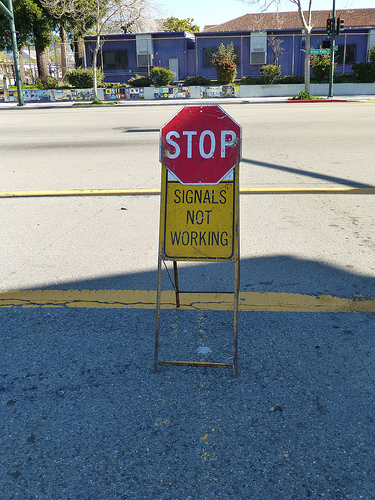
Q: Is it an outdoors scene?
A: Yes, it is outdoors.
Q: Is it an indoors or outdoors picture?
A: It is outdoors.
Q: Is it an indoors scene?
A: No, it is outdoors.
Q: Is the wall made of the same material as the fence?
A: No, the wall is made of cement and the fence is made of metal.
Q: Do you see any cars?
A: No, there are no cars.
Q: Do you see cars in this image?
A: No, there are no cars.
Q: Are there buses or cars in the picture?
A: No, there are no cars or buses.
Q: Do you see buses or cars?
A: No, there are no cars or buses.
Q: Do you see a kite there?
A: No, there are no kites.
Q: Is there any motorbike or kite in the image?
A: No, there are no kites or motorcycles.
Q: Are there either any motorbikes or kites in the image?
A: No, there are no kites or motorbikes.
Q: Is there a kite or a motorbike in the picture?
A: No, there are no kites or motorcycles.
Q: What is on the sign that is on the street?
A: The letter is on the stop sign.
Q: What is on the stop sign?
A: The letter is on the stop sign.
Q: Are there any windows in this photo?
A: Yes, there is a window.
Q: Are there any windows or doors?
A: Yes, there is a window.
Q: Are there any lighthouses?
A: No, there are no lighthouses.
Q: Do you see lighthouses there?
A: No, there are no lighthouses.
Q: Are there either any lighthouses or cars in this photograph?
A: No, there are no lighthouses or cars.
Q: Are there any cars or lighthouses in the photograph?
A: No, there are no lighthouses or cars.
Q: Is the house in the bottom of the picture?
A: No, the house is in the top of the image.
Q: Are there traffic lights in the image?
A: Yes, there is a traffic light.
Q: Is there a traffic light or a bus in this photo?
A: Yes, there is a traffic light.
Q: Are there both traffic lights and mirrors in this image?
A: No, there is a traffic light but no mirrors.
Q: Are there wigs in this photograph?
A: No, there are no wigs.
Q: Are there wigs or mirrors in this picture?
A: No, there are no wigs or mirrors.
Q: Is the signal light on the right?
A: Yes, the signal light is on the right of the image.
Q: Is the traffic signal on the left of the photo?
A: No, the traffic signal is on the right of the image.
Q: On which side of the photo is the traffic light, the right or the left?
A: The traffic light is on the right of the image.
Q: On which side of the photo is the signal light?
A: The signal light is on the right of the image.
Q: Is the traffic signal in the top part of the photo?
A: Yes, the traffic signal is in the top of the image.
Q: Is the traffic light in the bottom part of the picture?
A: No, the traffic light is in the top of the image.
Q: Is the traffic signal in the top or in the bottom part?
A: The traffic signal is in the top of the image.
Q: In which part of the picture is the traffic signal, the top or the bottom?
A: The traffic signal is in the top of the image.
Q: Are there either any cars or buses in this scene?
A: No, there are no cars or buses.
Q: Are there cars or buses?
A: No, there are no cars or buses.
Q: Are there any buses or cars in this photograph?
A: No, there are no cars or buses.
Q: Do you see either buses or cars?
A: No, there are no cars or buses.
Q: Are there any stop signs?
A: Yes, there is a stop sign.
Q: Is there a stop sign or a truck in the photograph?
A: Yes, there is a stop sign.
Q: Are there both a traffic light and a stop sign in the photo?
A: Yes, there are both a stop sign and a traffic light.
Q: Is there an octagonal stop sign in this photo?
A: Yes, there is an octagonal stop sign.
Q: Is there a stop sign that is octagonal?
A: Yes, there is a stop sign that is octagonal.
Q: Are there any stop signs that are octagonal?
A: Yes, there is a stop sign that is octagonal.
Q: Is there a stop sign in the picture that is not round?
A: Yes, there is a octagonal stop sign.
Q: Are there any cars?
A: No, there are no cars.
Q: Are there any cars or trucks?
A: No, there are no cars or trucks.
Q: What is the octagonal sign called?
A: The sign is a stop sign.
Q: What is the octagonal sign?
A: The sign is a stop sign.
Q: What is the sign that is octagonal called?
A: The sign is a stop sign.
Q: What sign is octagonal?
A: The sign is a stop sign.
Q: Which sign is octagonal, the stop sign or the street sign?
A: The stop sign is octagonal.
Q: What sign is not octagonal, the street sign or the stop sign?
A: The street sign is not octagonal.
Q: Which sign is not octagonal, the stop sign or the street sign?
A: The street sign is not octagonal.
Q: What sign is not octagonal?
A: The sign is a street sign.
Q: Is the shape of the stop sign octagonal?
A: Yes, the stop sign is octagonal.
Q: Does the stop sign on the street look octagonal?
A: Yes, the stop sign is octagonal.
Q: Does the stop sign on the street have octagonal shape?
A: Yes, the stop sign is octagonal.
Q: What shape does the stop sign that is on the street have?
A: The stop sign has octagonal shape.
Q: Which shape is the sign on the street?
A: The stop sign is octagonal.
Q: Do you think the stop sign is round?
A: No, the stop sign is octagonal.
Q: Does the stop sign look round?
A: No, the stop sign is octagonal.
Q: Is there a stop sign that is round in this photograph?
A: No, there is a stop sign but it is octagonal.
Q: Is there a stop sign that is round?
A: No, there is a stop sign but it is octagonal.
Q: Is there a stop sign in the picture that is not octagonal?
A: No, there is a stop sign but it is octagonal.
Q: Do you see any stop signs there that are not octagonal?
A: No, there is a stop sign but it is octagonal.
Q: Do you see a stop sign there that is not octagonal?
A: No, there is a stop sign but it is octagonal.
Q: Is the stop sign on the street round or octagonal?
A: The stop sign is octagonal.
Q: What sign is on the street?
A: The sign is a stop sign.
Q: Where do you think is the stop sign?
A: The stop sign is on the street.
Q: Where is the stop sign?
A: The stop sign is on the street.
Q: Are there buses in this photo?
A: No, there are no buses.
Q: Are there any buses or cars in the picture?
A: No, there are no buses or cars.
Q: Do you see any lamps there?
A: No, there are no lamps.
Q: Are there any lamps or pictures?
A: No, there are no lamps or pictures.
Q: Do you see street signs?
A: Yes, there is a street sign.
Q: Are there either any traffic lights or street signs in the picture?
A: Yes, there is a street sign.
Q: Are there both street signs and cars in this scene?
A: No, there is a street sign but no cars.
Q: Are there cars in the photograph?
A: No, there are no cars.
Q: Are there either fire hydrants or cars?
A: No, there are no cars or fire hydrants.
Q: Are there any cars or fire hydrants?
A: No, there are no cars or fire hydrants.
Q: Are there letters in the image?
A: Yes, there are letters.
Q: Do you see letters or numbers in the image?
A: Yes, there are letters.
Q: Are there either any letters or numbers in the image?
A: Yes, there are letters.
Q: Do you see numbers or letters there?
A: Yes, there are letters.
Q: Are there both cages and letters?
A: No, there are letters but no cages.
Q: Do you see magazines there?
A: No, there are no magazines.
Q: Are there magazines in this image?
A: No, there are no magazines.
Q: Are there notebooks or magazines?
A: No, there are no magazines or notebooks.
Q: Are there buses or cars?
A: No, there are no cars or buses.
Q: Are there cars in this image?
A: No, there are no cars.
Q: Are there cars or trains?
A: No, there are no cars or trains.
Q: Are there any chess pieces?
A: No, there are no chess pieces.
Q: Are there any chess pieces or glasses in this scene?
A: No, there are no chess pieces or glasses.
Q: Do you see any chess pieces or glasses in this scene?
A: No, there are no chess pieces or glasses.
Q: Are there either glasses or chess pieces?
A: No, there are no chess pieces or glasses.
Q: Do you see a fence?
A: Yes, there is a fence.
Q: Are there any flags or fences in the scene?
A: Yes, there is a fence.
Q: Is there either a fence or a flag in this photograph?
A: Yes, there is a fence.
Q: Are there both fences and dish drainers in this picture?
A: No, there is a fence but no dish drainers.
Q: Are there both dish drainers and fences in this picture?
A: No, there is a fence but no dish drainers.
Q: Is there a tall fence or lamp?
A: Yes, there is a tall fence.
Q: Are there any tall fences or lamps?
A: Yes, there is a tall fence.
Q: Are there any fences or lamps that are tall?
A: Yes, the fence is tall.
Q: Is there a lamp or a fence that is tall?
A: Yes, the fence is tall.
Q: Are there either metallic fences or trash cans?
A: Yes, there is a metal fence.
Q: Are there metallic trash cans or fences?
A: Yes, there is a metal fence.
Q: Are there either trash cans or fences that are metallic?
A: Yes, the fence is metallic.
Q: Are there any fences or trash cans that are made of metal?
A: Yes, the fence is made of metal.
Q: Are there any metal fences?
A: Yes, there is a metal fence.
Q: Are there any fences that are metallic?
A: Yes, there is a fence that is metallic.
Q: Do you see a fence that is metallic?
A: Yes, there is a fence that is metallic.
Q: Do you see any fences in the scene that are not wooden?
A: Yes, there is a metallic fence.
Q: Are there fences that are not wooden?
A: Yes, there is a metallic fence.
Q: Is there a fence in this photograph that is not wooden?
A: Yes, there is a metallic fence.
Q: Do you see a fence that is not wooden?
A: Yes, there is a metallic fence.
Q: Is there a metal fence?
A: Yes, there is a fence that is made of metal.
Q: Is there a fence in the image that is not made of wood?
A: Yes, there is a fence that is made of metal.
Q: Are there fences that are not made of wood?
A: Yes, there is a fence that is made of metal.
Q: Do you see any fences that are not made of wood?
A: Yes, there is a fence that is made of metal.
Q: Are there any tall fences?
A: Yes, there is a tall fence.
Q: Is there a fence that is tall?
A: Yes, there is a fence that is tall.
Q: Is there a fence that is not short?
A: Yes, there is a tall fence.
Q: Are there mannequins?
A: No, there are no mannequins.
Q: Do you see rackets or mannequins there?
A: No, there are no mannequins or rackets.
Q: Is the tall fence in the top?
A: Yes, the fence is in the top of the image.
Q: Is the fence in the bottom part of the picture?
A: No, the fence is in the top of the image.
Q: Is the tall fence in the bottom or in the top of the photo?
A: The fence is in the top of the image.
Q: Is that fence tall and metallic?
A: Yes, the fence is tall and metallic.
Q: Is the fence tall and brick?
A: No, the fence is tall but metallic.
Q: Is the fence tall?
A: Yes, the fence is tall.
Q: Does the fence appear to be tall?
A: Yes, the fence is tall.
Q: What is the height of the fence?
A: The fence is tall.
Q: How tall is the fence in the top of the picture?
A: The fence is tall.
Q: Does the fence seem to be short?
A: No, the fence is tall.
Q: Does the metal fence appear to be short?
A: No, the fence is tall.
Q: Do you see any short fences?
A: No, there is a fence but it is tall.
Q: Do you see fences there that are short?
A: No, there is a fence but it is tall.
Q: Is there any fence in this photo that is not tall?
A: No, there is a fence but it is tall.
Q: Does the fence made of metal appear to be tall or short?
A: The fence is tall.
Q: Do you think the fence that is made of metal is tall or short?
A: The fence is tall.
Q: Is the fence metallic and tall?
A: Yes, the fence is metallic and tall.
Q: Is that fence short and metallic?
A: No, the fence is metallic but tall.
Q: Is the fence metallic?
A: Yes, the fence is metallic.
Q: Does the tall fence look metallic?
A: Yes, the fence is metallic.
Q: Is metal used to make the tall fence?
A: Yes, the fence is made of metal.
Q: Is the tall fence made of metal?
A: Yes, the fence is made of metal.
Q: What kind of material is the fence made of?
A: The fence is made of metal.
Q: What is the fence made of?
A: The fence is made of metal.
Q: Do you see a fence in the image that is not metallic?
A: No, there is a fence but it is metallic.